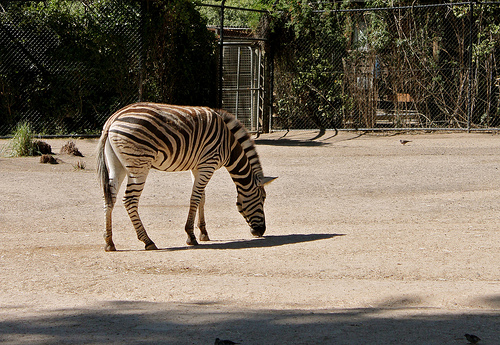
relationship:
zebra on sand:
[92, 93, 272, 251] [0, 131, 499, 343]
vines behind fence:
[351, 15, 491, 141] [317, 10, 496, 128]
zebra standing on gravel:
[92, 101, 280, 251] [12, 154, 499, 339]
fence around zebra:
[182, 28, 497, 124] [92, 93, 272, 251]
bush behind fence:
[27, 3, 117, 15] [6, 5, 220, 136]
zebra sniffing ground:
[92, 101, 280, 251] [15, 142, 490, 319]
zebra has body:
[92, 101, 280, 251] [73, 107, 230, 243]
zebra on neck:
[92, 93, 272, 251] [220, 144, 268, 185]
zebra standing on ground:
[92, 93, 272, 251] [0, 126, 498, 323]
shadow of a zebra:
[155, 233, 347, 252] [92, 101, 280, 251]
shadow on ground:
[155, 233, 347, 252] [0, 126, 498, 323]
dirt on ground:
[11, 155, 86, 172] [0, 126, 498, 323]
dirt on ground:
[39, 155, 86, 170] [7, 152, 496, 311]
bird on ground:
[395, 133, 409, 148] [0, 126, 498, 323]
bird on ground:
[399, 139, 413, 146] [0, 124, 493, 341]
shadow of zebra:
[148, 223, 345, 259] [92, 93, 272, 251]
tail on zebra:
[93, 129, 114, 208] [92, 93, 272, 251]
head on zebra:
[234, 180, 270, 229] [92, 93, 272, 251]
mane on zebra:
[219, 106, 277, 182] [71, 88, 353, 273]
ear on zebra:
[254, 172, 279, 192] [92, 101, 280, 251]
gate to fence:
[222, 43, 262, 133] [196, 2, 498, 137]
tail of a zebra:
[89, 129, 114, 206] [92, 101, 280, 251]